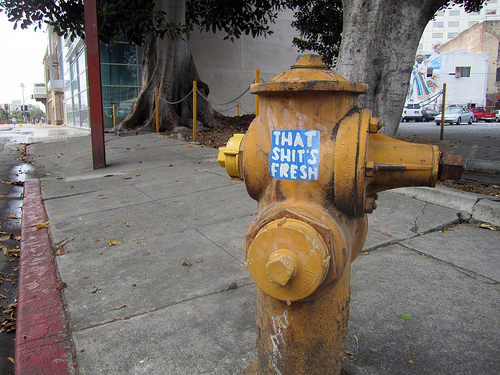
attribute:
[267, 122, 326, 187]
sign — blue, vulgar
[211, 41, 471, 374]
fire hydrant — yellow, brown, old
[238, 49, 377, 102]
top — yellow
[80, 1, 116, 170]
pole — tall, red, square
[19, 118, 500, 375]
sidewalk — grey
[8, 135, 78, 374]
edge — red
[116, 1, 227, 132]
trunk — grey, thick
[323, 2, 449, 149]
trunk — grey, thick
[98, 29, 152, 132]
window — blue, glass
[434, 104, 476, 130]
car — white, gray, silver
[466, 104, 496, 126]
car — red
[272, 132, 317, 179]
writing — white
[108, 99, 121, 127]
post — yellow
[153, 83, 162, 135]
post — yellow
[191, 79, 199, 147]
post — yellow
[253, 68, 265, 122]
post — yellow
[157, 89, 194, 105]
chain — metal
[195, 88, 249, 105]
chain — metal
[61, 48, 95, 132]
window — glass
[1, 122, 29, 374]
street — rundown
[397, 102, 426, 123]
van — white